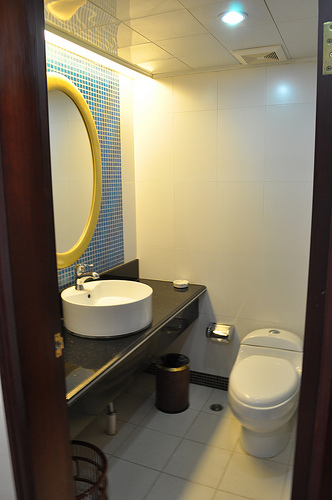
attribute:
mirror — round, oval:
[46, 71, 103, 267]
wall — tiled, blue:
[35, 33, 134, 291]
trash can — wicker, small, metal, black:
[155, 351, 191, 415]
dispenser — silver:
[205, 321, 234, 346]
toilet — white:
[227, 324, 303, 458]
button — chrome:
[269, 327, 280, 337]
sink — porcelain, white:
[61, 280, 155, 340]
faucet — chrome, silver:
[74, 264, 101, 290]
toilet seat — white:
[229, 353, 297, 406]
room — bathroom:
[2, 8, 330, 499]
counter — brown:
[57, 284, 207, 397]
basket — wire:
[68, 437, 117, 499]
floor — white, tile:
[72, 367, 300, 499]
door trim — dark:
[6, 3, 74, 388]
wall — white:
[134, 79, 329, 369]